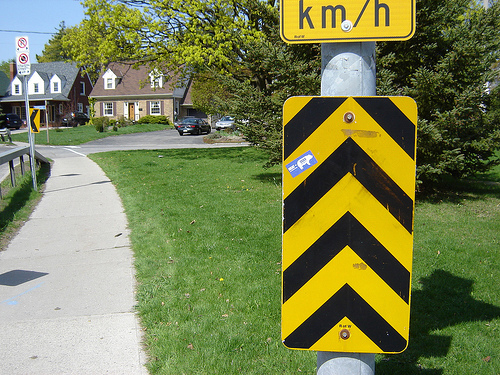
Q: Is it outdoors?
A: Yes, it is outdoors.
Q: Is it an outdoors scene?
A: Yes, it is outdoors.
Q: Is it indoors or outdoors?
A: It is outdoors.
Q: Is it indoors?
A: No, it is outdoors.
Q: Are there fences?
A: No, there are no fences.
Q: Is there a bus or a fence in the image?
A: No, there are no fences or buses.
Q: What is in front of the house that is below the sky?
A: The sign is in front of the house.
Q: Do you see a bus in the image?
A: No, there are no buses.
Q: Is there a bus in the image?
A: No, there are no buses.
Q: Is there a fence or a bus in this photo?
A: No, there are no buses or fences.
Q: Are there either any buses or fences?
A: No, there are no buses or fences.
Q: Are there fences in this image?
A: No, there are no fences.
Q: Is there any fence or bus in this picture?
A: No, there are no fences or buses.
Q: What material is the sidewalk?
A: The sidewalk is made of concrete.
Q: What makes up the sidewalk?
A: The sidewalk is made of concrete.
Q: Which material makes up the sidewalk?
A: The sidewalk is made of concrete.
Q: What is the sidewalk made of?
A: The sidewalk is made of concrete.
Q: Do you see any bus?
A: No, there are no buses.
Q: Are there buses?
A: No, there are no buses.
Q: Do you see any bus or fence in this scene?
A: No, there are no buses or fences.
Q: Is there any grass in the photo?
A: Yes, there is grass.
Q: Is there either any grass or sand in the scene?
A: Yes, there is grass.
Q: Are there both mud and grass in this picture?
A: No, there is grass but no mud.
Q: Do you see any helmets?
A: No, there are no helmets.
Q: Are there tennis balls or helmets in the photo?
A: No, there are no helmets or tennis balls.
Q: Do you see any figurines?
A: No, there are no figurines.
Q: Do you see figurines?
A: No, there are no figurines.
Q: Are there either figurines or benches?
A: No, there are no figurines or benches.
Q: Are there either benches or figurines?
A: No, there are no figurines or benches.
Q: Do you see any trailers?
A: No, there are no trailers.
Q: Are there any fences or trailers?
A: No, there are no trailers or fences.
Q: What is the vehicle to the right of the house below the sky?
A: The vehicle is a car.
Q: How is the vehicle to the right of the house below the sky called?
A: The vehicle is a car.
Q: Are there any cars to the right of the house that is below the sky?
A: Yes, there is a car to the right of the house.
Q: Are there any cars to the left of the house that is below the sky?
A: No, the car is to the right of the house.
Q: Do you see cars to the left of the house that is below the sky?
A: No, the car is to the right of the house.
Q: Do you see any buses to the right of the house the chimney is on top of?
A: No, there is a car to the right of the house.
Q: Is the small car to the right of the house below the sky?
A: Yes, the car is to the right of the house.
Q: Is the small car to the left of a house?
A: No, the car is to the right of a house.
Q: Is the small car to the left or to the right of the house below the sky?
A: The car is to the right of the house.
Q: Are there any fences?
A: No, there are no fences.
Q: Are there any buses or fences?
A: No, there are no fences or buses.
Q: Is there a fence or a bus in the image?
A: No, there are no fences or buses.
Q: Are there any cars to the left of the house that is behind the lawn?
A: Yes, there is a car to the left of the house.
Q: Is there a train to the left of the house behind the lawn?
A: No, there is a car to the left of the house.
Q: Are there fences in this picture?
A: No, there are no fences.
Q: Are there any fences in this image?
A: No, there are no fences.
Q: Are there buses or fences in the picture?
A: No, there are no fences or buses.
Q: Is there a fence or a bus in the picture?
A: No, there are no fences or buses.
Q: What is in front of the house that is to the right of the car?
A: The sign is in front of the house.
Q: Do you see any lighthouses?
A: No, there are no lighthouses.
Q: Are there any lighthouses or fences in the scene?
A: No, there are no lighthouses or fences.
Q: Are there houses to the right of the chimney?
A: Yes, there is a house to the right of the chimney.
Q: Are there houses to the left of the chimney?
A: No, the house is to the right of the chimney.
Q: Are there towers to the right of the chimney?
A: No, there is a house to the right of the chimney.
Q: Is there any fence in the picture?
A: No, there are no fences.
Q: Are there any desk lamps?
A: No, there are no desk lamps.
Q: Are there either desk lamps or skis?
A: No, there are no desk lamps or skis.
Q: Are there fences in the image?
A: No, there are no fences.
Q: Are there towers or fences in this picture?
A: No, there are no fences or towers.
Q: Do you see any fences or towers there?
A: No, there are no fences or towers.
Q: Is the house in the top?
A: Yes, the house is in the top of the image.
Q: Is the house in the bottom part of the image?
A: No, the house is in the top of the image.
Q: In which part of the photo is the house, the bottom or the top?
A: The house is in the top of the image.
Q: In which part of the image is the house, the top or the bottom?
A: The house is in the top of the image.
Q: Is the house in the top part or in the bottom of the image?
A: The house is in the top of the image.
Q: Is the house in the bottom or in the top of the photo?
A: The house is in the top of the image.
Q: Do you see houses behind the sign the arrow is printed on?
A: Yes, there is a house behind the sign.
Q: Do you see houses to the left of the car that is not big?
A: Yes, there is a house to the left of the car.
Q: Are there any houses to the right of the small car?
A: No, the house is to the left of the car.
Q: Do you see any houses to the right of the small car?
A: No, the house is to the left of the car.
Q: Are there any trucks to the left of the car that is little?
A: No, there is a house to the left of the car.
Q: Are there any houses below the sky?
A: Yes, there is a house below the sky.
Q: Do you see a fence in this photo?
A: No, there are no fences.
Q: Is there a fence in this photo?
A: No, there are no fences.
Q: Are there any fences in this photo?
A: No, there are no fences.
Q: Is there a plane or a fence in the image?
A: No, there are no fences or airplanes.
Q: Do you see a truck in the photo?
A: No, there are no trucks.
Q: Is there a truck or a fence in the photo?
A: No, there are no trucks or fences.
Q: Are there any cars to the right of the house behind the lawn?
A: Yes, there is a car to the right of the house.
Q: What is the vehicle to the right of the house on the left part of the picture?
A: The vehicle is a car.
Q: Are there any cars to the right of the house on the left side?
A: Yes, there is a car to the right of the house.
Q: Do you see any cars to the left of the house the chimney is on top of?
A: No, the car is to the right of the house.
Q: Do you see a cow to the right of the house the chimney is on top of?
A: No, there is a car to the right of the house.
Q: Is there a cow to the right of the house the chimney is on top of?
A: No, there is a car to the right of the house.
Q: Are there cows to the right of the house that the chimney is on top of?
A: No, there is a car to the right of the house.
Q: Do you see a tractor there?
A: No, there are no tractors.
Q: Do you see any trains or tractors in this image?
A: No, there are no tractors or trains.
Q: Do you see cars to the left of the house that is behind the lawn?
A: Yes, there is a car to the left of the house.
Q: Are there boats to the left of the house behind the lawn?
A: No, there is a car to the left of the house.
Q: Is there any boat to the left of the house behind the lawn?
A: No, there is a car to the left of the house.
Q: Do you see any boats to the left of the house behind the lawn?
A: No, there is a car to the left of the house.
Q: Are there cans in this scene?
A: No, there are no cans.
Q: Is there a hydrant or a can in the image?
A: No, there are no cans or fire hydrants.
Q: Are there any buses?
A: No, there are no buses.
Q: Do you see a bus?
A: No, there are no buses.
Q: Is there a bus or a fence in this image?
A: No, there are no buses or fences.